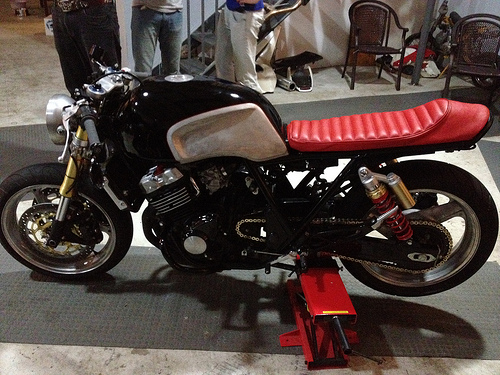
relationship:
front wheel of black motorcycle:
[4, 164, 132, 281] [0, 45, 499, 297]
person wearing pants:
[215, 0, 265, 92] [214, 4, 265, 94]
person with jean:
[131, 50, 186, 82] [136, 7, 196, 109]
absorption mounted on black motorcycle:
[356, 166, 415, 242] [0, 45, 499, 297]